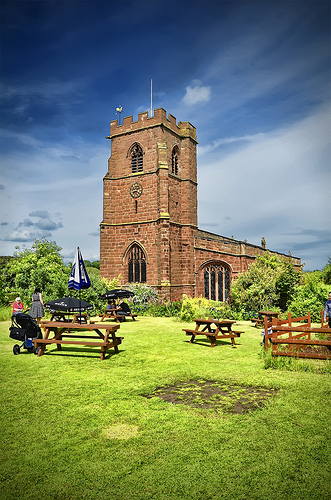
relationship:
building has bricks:
[98, 105, 306, 317] [147, 222, 188, 286]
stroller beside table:
[8, 309, 45, 358] [29, 310, 123, 366]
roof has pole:
[104, 107, 199, 148] [145, 73, 157, 115]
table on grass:
[29, 310, 123, 366] [0, 313, 331, 499]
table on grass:
[176, 309, 246, 354] [0, 313, 331, 499]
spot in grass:
[98, 418, 143, 446] [0, 313, 331, 499]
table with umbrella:
[29, 310, 123, 366] [66, 244, 91, 292]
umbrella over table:
[44, 297, 94, 315] [29, 310, 123, 366]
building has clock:
[98, 105, 306, 317] [126, 183, 145, 199]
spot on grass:
[98, 418, 143, 446] [0, 313, 331, 499]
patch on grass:
[136, 371, 287, 418] [0, 313, 331, 499]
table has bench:
[29, 310, 123, 366] [32, 337, 114, 349]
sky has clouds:
[1, 2, 330, 263] [0, 78, 331, 262]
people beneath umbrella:
[98, 298, 135, 321] [99, 288, 135, 301]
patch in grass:
[136, 371, 287, 418] [0, 313, 331, 499]